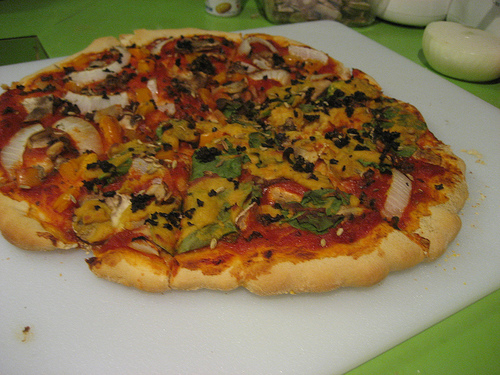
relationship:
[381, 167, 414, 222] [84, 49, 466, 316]
onion on pizza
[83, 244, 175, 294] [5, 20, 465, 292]
crust on pizza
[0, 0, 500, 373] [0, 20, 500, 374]
table cloth under cutting board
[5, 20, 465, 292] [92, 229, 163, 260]
pizza has sauce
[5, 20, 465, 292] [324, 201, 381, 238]
pizza has sauce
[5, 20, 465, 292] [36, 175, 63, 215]
pizza has sauce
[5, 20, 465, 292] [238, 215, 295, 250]
pizza has sauce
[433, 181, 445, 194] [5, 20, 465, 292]
pepper on pizza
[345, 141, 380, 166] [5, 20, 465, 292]
pepper on pizza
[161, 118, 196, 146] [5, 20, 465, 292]
pepper on pizza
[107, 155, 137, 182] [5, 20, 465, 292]
pepper on pizza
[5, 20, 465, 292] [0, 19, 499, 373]
pizza on plate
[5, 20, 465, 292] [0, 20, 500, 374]
pizza on cutting board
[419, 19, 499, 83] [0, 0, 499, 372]
onion on counter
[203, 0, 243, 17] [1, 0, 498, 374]
salt shaker on table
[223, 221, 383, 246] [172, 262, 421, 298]
sauce on crust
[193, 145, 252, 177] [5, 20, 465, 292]
green spinach on pizza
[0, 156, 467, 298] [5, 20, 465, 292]
crust on pizza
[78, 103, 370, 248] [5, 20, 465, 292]
mustard on pizza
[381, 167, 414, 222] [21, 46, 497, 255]
onion on pizza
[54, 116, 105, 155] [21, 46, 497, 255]
onion on pizza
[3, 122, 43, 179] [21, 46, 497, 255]
onion on pizza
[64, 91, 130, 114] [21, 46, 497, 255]
onion on pizza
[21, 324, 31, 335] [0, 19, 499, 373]
crumb on plate